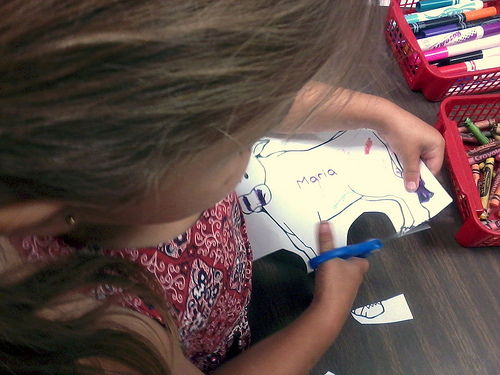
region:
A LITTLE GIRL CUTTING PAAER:
[7, 8, 479, 365]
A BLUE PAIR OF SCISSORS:
[300, 214, 436, 272]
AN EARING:
[43, 204, 85, 238]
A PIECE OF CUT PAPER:
[349, 290, 416, 338]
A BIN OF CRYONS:
[429, 86, 498, 260]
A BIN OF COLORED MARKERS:
[374, 3, 497, 93]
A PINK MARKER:
[418, 36, 498, 63]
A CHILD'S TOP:
[15, 188, 267, 369]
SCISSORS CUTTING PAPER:
[215, 124, 460, 277]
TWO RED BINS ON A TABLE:
[371, 3, 498, 257]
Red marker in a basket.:
[435, 61, 482, 72]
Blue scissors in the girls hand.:
[316, 217, 461, 283]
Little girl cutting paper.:
[132, 62, 435, 367]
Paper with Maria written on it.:
[284, 163, 352, 211]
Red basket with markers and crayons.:
[409, 47, 498, 97]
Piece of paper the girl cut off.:
[350, 295, 440, 345]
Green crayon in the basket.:
[463, 117, 488, 157]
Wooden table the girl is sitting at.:
[438, 256, 490, 363]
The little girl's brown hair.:
[116, 55, 241, 116]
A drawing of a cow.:
[250, 147, 415, 249]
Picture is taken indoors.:
[13, 74, 463, 368]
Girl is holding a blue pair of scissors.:
[304, 218, 429, 265]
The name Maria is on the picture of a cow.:
[266, 142, 427, 233]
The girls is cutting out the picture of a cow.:
[260, 121, 436, 248]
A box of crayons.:
[439, 96, 499, 257]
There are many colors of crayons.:
[447, 93, 497, 235]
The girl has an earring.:
[50, 202, 97, 247]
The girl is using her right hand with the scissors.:
[305, 80, 418, 326]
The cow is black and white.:
[268, 145, 486, 258]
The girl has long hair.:
[5, 96, 157, 372]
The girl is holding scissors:
[15, 8, 454, 339]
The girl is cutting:
[46, 27, 459, 340]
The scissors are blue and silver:
[298, 208, 467, 292]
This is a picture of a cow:
[248, 122, 441, 302]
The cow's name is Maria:
[196, 102, 434, 268]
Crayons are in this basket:
[437, 94, 495, 237]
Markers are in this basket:
[398, 8, 496, 92]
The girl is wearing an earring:
[13, 148, 121, 301]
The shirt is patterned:
[49, 124, 352, 359]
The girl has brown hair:
[15, 7, 431, 301]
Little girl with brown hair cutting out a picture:
[0, 1, 445, 373]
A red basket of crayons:
[435, 98, 499, 249]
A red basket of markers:
[384, 0, 499, 92]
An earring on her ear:
[63, 214, 80, 231]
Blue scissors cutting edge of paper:
[308, 215, 431, 270]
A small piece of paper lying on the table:
[352, 294, 429, 327]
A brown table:
[412, 248, 498, 373]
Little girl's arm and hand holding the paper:
[281, 81, 445, 199]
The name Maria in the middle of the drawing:
[290, 163, 350, 193]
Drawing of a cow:
[235, 143, 450, 270]